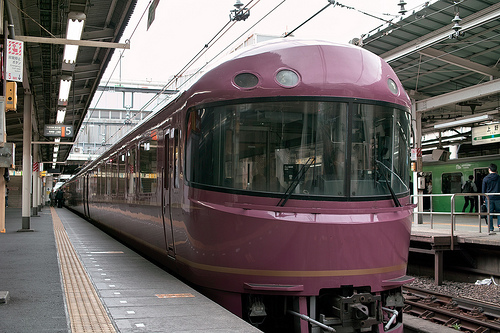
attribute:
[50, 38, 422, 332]
train — purple, stopped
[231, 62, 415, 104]
headlights — round, off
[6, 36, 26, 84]
sign — white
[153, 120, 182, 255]
door — closed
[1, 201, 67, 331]
pavement — black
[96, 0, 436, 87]
sky — white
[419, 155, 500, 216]
building — green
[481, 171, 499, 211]
jacket — black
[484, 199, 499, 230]
pants — blue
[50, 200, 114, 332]
barrier — yellow